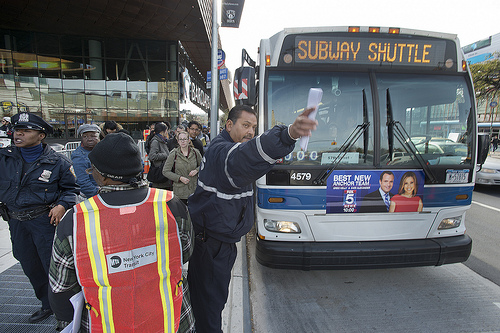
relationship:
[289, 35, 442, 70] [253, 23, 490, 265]
screen on bus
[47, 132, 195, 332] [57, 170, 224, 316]
man wearing vest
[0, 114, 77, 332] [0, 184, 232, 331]
officer standing on sidewalk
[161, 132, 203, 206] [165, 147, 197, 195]
lady wearing jacket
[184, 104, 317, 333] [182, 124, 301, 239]
man wearing jacket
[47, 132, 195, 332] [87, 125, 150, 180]
man wearing hat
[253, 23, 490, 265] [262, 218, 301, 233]
bus has headlight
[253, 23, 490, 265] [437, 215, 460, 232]
bus has headlight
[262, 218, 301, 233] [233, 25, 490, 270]
headlight on bus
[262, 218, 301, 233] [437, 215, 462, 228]
headlight to right of headlight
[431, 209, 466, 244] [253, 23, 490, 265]
headlight on bus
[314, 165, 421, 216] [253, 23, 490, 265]
advertisement on bus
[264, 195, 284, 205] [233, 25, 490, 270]
light on bus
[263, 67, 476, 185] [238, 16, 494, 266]
windshield on bus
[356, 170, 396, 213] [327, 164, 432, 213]
man on sign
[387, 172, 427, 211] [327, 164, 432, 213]
lady on sign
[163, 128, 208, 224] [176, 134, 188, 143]
lady wearing eyeglasses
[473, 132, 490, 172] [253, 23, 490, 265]
mirror on bus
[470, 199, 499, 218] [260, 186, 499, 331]
line on street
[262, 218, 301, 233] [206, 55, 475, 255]
headlight on front of bus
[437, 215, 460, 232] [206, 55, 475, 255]
headlight on front of bus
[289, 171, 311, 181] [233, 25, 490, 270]
number on front of bus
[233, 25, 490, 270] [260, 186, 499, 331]
bus riding down street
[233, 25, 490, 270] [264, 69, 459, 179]
bus with windshield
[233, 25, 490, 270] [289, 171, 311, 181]
bus with number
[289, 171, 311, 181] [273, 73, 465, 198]
number in window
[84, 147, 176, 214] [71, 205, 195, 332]
man wearing vest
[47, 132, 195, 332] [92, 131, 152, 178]
man wearing hat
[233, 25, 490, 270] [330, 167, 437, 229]
bus with advertising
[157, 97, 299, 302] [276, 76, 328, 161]
man holding papers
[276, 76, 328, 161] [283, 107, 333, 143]
papers in hand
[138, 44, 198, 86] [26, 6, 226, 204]
window of building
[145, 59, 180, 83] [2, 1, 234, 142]
window of building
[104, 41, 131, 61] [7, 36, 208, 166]
window of building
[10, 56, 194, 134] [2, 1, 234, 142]
window of building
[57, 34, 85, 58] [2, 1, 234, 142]
window of building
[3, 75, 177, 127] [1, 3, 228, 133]
window of building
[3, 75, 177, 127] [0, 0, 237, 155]
window of building